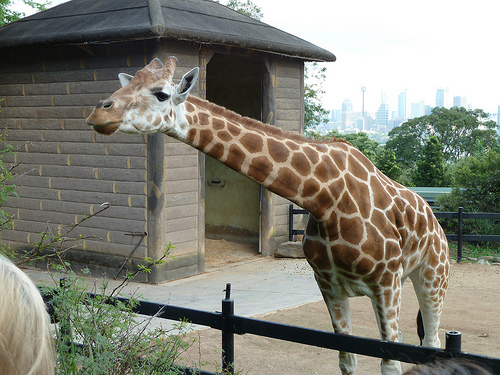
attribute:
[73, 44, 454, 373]
giraffe — curious, white, brown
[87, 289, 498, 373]
fence is painted — metal, black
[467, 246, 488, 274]
small stone — structure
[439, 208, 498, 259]
low fenced area — dark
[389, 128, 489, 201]
trees in the distanc — distant